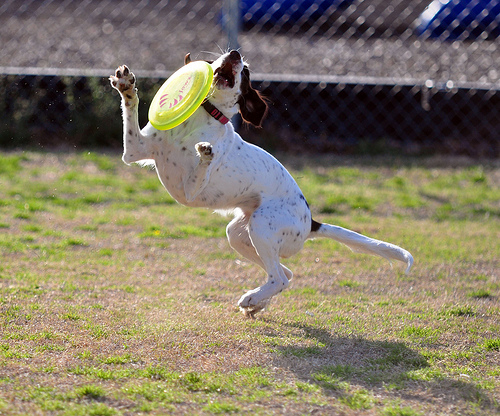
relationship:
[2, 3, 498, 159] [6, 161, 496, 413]
fenced around field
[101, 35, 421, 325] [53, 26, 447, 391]
dog in air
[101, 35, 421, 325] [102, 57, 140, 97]
dog has paw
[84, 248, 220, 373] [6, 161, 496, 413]
patches on field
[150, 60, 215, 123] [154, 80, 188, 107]
frisbee with pattern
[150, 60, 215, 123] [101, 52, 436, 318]
frisbee hitting dog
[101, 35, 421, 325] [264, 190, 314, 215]
dog with spots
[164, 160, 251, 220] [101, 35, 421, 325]
chest of dog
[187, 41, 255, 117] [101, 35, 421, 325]
face of dog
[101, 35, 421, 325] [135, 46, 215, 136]
dog catch frisbee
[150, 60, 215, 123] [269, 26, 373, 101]
frisbee in air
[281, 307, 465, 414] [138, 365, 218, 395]
shadow on grass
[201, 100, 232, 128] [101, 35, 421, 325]
collar on dog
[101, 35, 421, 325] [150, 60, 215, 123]
dog playing with frisbee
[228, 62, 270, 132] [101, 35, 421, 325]
ears on dog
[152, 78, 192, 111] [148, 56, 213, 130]
design on frisbee